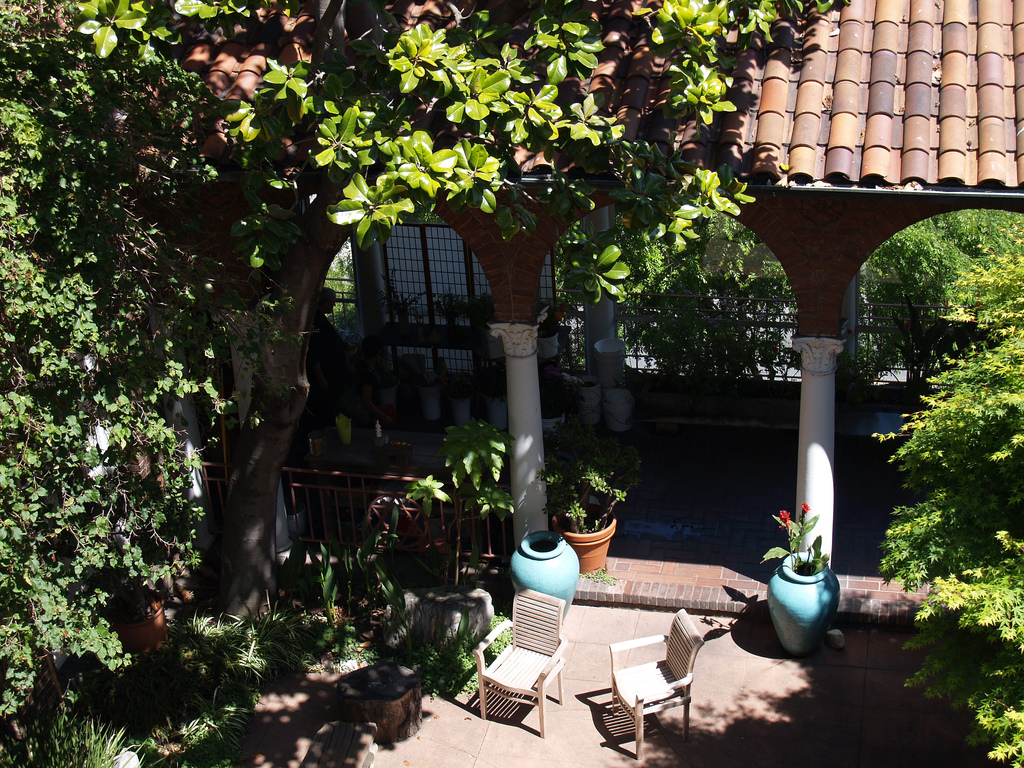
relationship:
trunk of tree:
[222, 454, 298, 565] [65, 357, 349, 615]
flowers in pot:
[757, 499, 834, 585] [760, 547, 847, 643]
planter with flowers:
[761, 548, 845, 662] [760, 495, 821, 575]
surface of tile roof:
[734, 103, 951, 129] [767, 203, 1009, 217]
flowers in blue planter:
[757, 499, 834, 585] [767, 568, 854, 709]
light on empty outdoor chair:
[598, 604, 735, 768] [568, 574, 746, 768]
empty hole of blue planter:
[508, 539, 588, 561] [491, 479, 584, 560]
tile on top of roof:
[815, 67, 882, 132] [698, 0, 1018, 202]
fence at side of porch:
[585, 283, 916, 385] [281, 393, 945, 558]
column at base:
[786, 332, 854, 588] [815, 566, 854, 655]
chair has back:
[594, 585, 718, 765] [653, 609, 718, 690]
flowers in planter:
[776, 520, 818, 575] [776, 567, 833, 630]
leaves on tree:
[294, 90, 500, 238] [357, 6, 632, 450]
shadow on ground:
[463, 704, 535, 726] [409, 719, 489, 763]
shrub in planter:
[566, 475, 616, 542] [560, 531, 628, 571]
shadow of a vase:
[720, 579, 790, 660] [763, 551, 841, 657]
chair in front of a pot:
[469, 590, 569, 735] [510, 526, 577, 615]